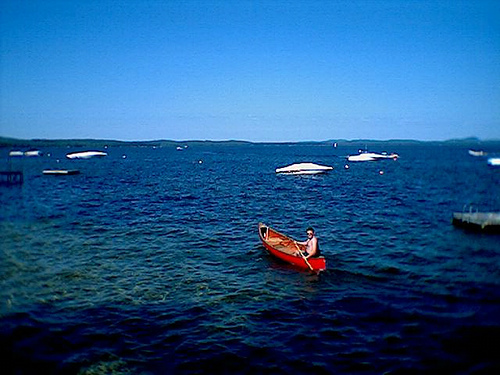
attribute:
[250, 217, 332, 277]
boat — red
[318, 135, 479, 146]
land — distant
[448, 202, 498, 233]
pier — wooden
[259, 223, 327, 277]
canoe — red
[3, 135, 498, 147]
land — distant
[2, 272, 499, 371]
shadow — dark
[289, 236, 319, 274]
paddle — long, narrow, wooden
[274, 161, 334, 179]
boat — white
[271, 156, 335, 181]
boat — white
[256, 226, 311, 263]
boat — red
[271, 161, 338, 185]
boat — white covered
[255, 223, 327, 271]
canoe — bright red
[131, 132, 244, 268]
water — blue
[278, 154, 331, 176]
boat — white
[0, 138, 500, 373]
water — dark blue, wavy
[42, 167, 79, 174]
flat dock — square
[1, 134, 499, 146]
shore — distant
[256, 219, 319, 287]
boat — red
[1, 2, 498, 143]
sky — blue, brilliant, clear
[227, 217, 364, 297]
boat — red